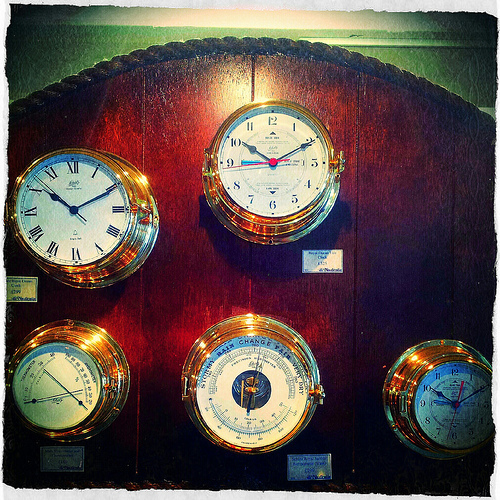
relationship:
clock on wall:
[199, 99, 346, 251] [12, 9, 494, 488]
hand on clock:
[238, 139, 274, 164] [199, 99, 346, 251]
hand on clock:
[275, 137, 317, 166] [199, 99, 346, 251]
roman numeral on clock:
[64, 156, 80, 178] [11, 141, 162, 293]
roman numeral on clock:
[109, 204, 130, 217] [11, 141, 162, 293]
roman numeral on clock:
[68, 245, 84, 266] [11, 141, 162, 293]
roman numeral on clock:
[22, 206, 39, 217] [11, 141, 162, 293]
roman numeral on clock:
[46, 239, 61, 263] [11, 141, 162, 293]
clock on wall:
[11, 141, 162, 293] [12, 9, 494, 488]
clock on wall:
[376, 334, 491, 463] [12, 9, 494, 488]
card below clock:
[299, 250, 346, 279] [199, 99, 346, 251]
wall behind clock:
[12, 9, 494, 488] [199, 99, 346, 251]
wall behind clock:
[12, 9, 494, 488] [11, 141, 162, 293]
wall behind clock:
[12, 9, 494, 488] [376, 334, 491, 463]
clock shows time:
[199, 99, 346, 251] [227, 133, 316, 162]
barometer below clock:
[179, 310, 327, 461] [199, 99, 346, 251]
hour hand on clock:
[42, 186, 88, 227] [11, 141, 162, 293]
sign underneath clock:
[8, 276, 40, 304] [11, 141, 162, 293]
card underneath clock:
[299, 250, 346, 279] [199, 99, 346, 251]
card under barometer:
[283, 451, 336, 483] [179, 310, 327, 461]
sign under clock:
[8, 276, 40, 304] [11, 141, 162, 293]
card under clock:
[299, 250, 346, 279] [199, 99, 346, 251]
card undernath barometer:
[283, 451, 336, 483] [179, 310, 327, 461]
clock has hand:
[199, 99, 346, 251] [238, 139, 274, 164]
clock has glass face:
[199, 99, 346, 251] [217, 104, 333, 220]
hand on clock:
[431, 387, 456, 408] [376, 334, 491, 463]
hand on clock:
[459, 381, 495, 408] [376, 334, 491, 463]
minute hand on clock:
[79, 189, 115, 223] [11, 141, 162, 293]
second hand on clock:
[33, 173, 91, 228] [11, 141, 162, 293]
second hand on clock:
[222, 156, 293, 172] [199, 99, 346, 251]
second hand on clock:
[442, 379, 466, 447] [376, 334, 491, 463]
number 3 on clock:
[310, 156, 322, 169] [199, 99, 346, 251]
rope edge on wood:
[8, 33, 494, 133] [8, 37, 496, 489]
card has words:
[299, 250, 346, 279] [307, 250, 336, 267]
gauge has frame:
[14, 341, 104, 429] [7, 317, 136, 446]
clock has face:
[11, 141, 162, 293] [17, 154, 131, 266]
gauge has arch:
[14, 341, 104, 429] [62, 355, 96, 406]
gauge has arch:
[14, 341, 104, 429] [27, 356, 59, 407]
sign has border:
[8, 276, 40, 304] [7, 274, 40, 305]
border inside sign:
[7, 274, 40, 305] [8, 276, 40, 304]